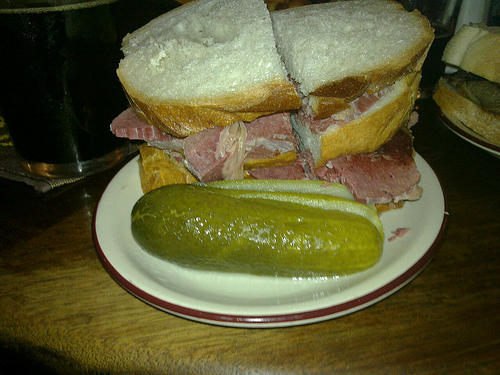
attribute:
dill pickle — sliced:
[113, 169, 409, 291]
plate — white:
[72, 180, 456, 335]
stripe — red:
[122, 261, 390, 343]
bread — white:
[123, 13, 300, 180]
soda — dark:
[17, 16, 118, 147]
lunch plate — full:
[73, 147, 451, 337]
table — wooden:
[1, 158, 499, 373]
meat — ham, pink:
[109, 75, 422, 208]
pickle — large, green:
[130, 175, 383, 275]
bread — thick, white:
[115, 2, 432, 140]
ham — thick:
[110, 78, 424, 208]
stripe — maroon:
[89, 147, 448, 327]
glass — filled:
[2, 2, 137, 177]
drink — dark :
[1, 1, 134, 162]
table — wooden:
[0, 12, 500, 372]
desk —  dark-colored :
[5, 120, 496, 370]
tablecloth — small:
[2, 137, 137, 191]